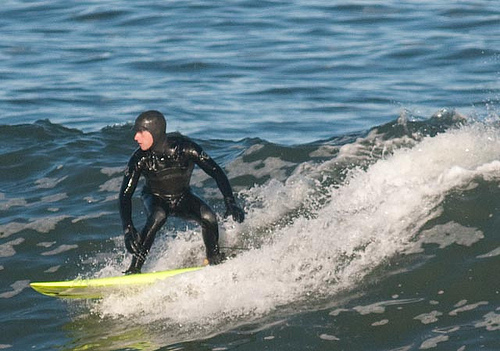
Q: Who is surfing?
A: A man.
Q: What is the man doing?
A: Catching a wave.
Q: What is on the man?
A: A wetsuit.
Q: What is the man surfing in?
A: The ocean.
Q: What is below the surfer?
A: A board.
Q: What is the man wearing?
A: A wetsuit.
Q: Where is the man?
A: In the water.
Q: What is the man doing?
A: Surfing.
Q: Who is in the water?
A: A man.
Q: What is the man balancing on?
A: A wave.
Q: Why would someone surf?
A: For fun.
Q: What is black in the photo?
A: The man's suit.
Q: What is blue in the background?
A: The water.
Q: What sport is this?
A: Surfing.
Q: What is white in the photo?
A: The foam.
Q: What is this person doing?
A: This person is surfing.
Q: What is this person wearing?
A: He is wearing a wetsuit.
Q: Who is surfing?
A: The man is surfing.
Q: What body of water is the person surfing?
A: The surfer is in the ocean.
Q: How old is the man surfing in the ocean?
A: The man is twenty years old.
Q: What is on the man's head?
A: The man is wearing a wet suit cap.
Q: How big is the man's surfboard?
A: The surfboard is six feet long.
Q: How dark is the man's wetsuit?
A: The man's wetsuit is dark black.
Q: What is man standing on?
A: Surfboard.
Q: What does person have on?
A: Wetsuit.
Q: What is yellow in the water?
A: Surfboard.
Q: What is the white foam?
A: Water.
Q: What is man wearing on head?
A: Swim cap.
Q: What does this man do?
A: Surfs.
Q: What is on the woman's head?
A: A black hood.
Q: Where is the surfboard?
A: In the water.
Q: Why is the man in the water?
A: Surfing.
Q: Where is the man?
A: In the water.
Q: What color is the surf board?
A: Yellow.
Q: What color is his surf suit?
A: Black.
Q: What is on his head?
A: A swim cap.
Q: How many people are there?
A: One.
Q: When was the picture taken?
A: In the daytime.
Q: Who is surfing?
A: A man.